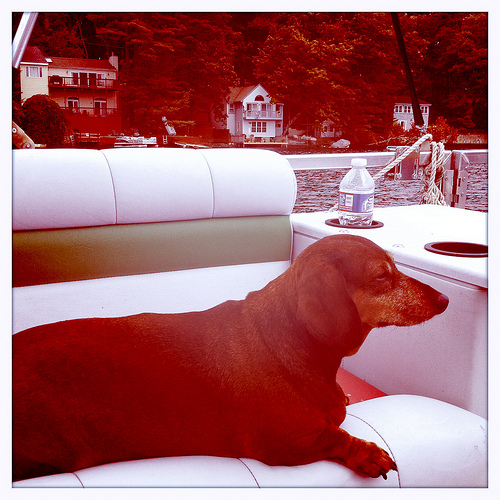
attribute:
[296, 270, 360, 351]
ear — long, brown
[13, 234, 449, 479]
dog — long, brown, pudgy, black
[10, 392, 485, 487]
cushion — white, boat cushion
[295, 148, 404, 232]
water — blue, lake water, slightly rough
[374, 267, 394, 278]
eye — black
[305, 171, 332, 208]
water — wavy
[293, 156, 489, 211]
water — wavy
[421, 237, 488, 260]
cup holder — black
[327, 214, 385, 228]
cup holder — black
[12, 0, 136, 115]
house — tan, brown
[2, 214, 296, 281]
cushion — green, white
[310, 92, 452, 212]
rope — white, frayed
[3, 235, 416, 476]
dog — brown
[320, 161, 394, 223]
bottle — water bottle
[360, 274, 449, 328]
muzzle — gray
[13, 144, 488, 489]
seat — boat seat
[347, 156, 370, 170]
top — white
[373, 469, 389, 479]
claw — black